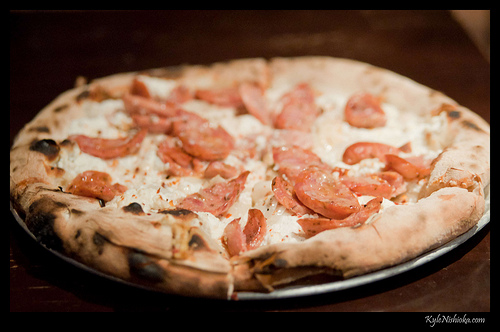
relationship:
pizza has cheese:
[14, 54, 497, 301] [63, 75, 450, 253]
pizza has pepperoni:
[14, 54, 497, 301] [66, 78, 431, 258]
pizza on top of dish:
[14, 54, 497, 301] [8, 168, 490, 300]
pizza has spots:
[14, 54, 497, 301] [12, 89, 345, 301]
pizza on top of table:
[14, 54, 497, 301] [12, 11, 493, 313]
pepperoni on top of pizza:
[66, 78, 431, 258] [14, 54, 497, 301]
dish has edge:
[8, 168, 490, 300] [7, 200, 414, 302]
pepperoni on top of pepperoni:
[295, 165, 358, 219] [271, 175, 312, 215]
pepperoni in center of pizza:
[182, 97, 333, 191] [14, 54, 497, 301]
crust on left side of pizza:
[8, 63, 236, 302] [14, 54, 497, 301]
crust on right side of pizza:
[244, 54, 495, 278] [14, 54, 497, 301]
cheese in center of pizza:
[223, 116, 322, 191] [14, 54, 497, 301]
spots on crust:
[12, 89, 345, 301] [8, 56, 490, 299]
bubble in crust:
[253, 186, 475, 288] [8, 56, 490, 299]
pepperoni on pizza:
[66, 78, 431, 258] [14, 54, 497, 301]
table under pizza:
[12, 11, 493, 313] [14, 54, 497, 301]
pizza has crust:
[14, 54, 497, 301] [8, 56, 490, 299]